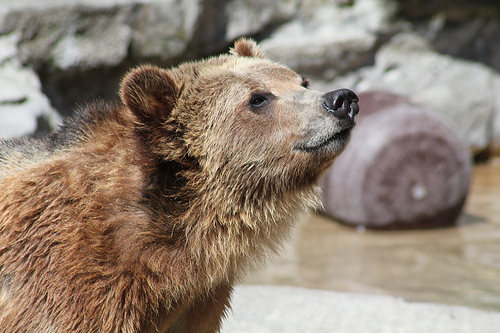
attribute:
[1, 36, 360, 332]
bear — brown, sniffing, fuzzy, fluffy, looking up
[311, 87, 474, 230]
barrel — purple, laying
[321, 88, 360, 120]
nose — black, large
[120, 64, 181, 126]
right ear — furry, short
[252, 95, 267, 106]
eye — black, small, dark brown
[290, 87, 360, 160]
muzzle — short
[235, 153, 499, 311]
water — clear, muddy, brown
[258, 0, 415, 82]
rock — brown, grey, large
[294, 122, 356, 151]
mouth — closed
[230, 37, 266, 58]
ear — small, round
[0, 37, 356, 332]
fur — prickly, black, short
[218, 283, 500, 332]
ground — brown